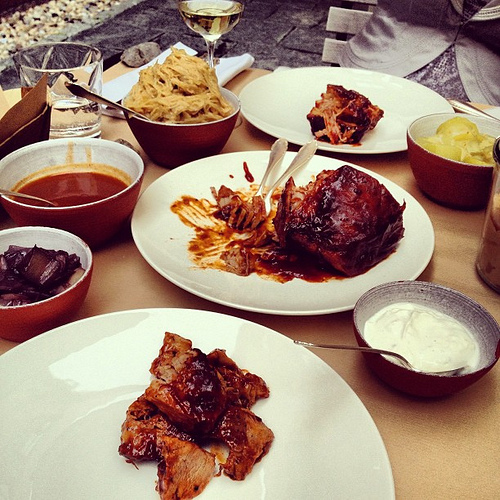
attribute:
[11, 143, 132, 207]
soup — red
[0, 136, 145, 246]
bowl — ceramic, red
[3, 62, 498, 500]
table — brown, tan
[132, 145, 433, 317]
plate — white, messy, big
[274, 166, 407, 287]
food — cooked, saucy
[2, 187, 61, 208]
spoon — metal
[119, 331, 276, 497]
meat — cooked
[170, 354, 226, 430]
sauce — red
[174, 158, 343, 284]
sauce — smeared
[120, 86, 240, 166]
bowl — dark, red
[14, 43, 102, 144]
glass — cut design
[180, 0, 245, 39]
wine — white, gold, light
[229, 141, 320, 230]
fork — sauce covered, metal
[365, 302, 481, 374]
cream — white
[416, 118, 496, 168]
pickles — green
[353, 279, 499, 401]
bowl — gray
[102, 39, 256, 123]
napkin — white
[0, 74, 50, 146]
napkin — brown